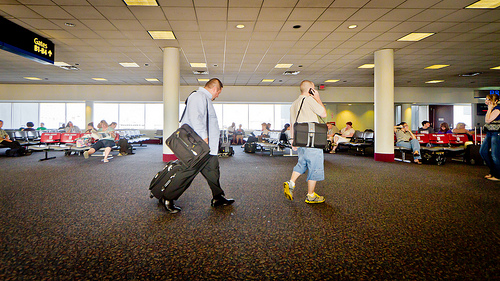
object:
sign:
[32, 37, 53, 58]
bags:
[165, 90, 210, 170]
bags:
[150, 154, 187, 201]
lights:
[399, 31, 435, 43]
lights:
[424, 64, 449, 70]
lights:
[358, 63, 375, 68]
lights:
[147, 31, 175, 42]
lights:
[123, 0, 161, 8]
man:
[157, 78, 235, 214]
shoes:
[305, 191, 327, 204]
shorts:
[293, 146, 325, 181]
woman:
[480, 86, 500, 182]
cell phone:
[307, 89, 317, 96]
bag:
[292, 96, 331, 149]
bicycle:
[419, 144, 454, 166]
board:
[0, 15, 56, 66]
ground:
[374, 85, 396, 120]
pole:
[372, 47, 394, 154]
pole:
[160, 47, 182, 163]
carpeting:
[203, 216, 497, 271]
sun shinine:
[41, 98, 194, 152]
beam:
[374, 45, 394, 163]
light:
[235, 24, 245, 29]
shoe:
[158, 197, 182, 213]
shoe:
[210, 196, 235, 207]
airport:
[3, 1, 498, 280]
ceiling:
[2, 0, 497, 85]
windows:
[3, 86, 474, 152]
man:
[284, 80, 330, 204]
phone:
[496, 100, 500, 103]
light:
[189, 62, 208, 67]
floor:
[3, 145, 499, 281]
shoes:
[281, 181, 296, 200]